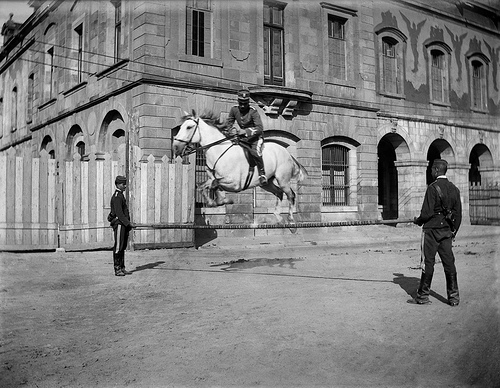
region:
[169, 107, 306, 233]
a white horse jumping through the air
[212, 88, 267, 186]
a man riding the white horse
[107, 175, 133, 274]
a man holding the left side of the pole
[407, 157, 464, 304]
a man holding the right side of the pole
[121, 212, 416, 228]
a long pole that the horse is jumping over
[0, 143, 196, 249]
a wooden fence behind the horse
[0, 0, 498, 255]
a large building behind the horse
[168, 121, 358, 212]
bars on the windows behind the horse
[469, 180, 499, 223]
a small wooden fence behind the man on the right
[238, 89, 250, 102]
a hat on the man who is riding the horse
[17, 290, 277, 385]
flat area of dirt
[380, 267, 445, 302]
man's foot and his shadow cast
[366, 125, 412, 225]
a building's archway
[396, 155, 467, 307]
man holding a pole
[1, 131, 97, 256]
a wooden fence with decorative top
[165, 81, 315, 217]
man in uniform riding a jumping horse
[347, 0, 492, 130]
facade of a building with designs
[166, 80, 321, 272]
rider and horse jumping over a raised pole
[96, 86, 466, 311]
two men holding a pole for a rider to jump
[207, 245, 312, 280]
shadow of a horse cast on the ground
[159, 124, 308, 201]
the horse is in the air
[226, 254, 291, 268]
the shadow is on the ground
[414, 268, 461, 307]
the boots are black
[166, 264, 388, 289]
the shadow pole is on the ground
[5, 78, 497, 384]
the photo is black and white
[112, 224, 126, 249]
the stripe is white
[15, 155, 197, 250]
the fene is wooden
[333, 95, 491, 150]
the building is made of stone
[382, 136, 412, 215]
the openning is dome shaped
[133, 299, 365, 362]
the ground is grey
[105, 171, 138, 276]
a soldier on the horse's right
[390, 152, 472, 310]
a soldier on the horse's left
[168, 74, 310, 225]
a horse and soldier jumping over a rod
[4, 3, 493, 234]
a large concrete building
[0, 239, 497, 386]
a dirt road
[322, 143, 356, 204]
bars in a window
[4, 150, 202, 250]
a wooden fence by a building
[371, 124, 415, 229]
an arched doorwy in a building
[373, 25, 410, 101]
an arched window on a building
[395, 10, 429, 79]
an angel on the side of a building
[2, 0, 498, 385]
The photo is in black and white.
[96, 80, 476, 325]
Three people are in the picture.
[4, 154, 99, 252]
A wooden fence is in the background.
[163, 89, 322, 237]
The horse is jumping.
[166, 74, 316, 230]
The horse is white.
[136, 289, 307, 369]
The ground is gray.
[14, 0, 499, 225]
A building is in the background.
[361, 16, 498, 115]
Windows are in the building.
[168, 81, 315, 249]
A person is riding a horse.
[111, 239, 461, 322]
A shadow is on the ground.